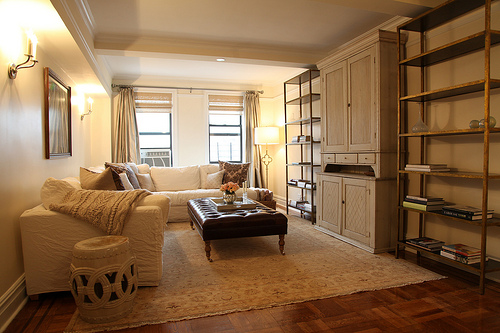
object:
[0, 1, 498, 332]
living room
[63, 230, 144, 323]
basket style table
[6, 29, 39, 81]
sconce lights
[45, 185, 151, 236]
blanket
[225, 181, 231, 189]
flowers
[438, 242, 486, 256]
books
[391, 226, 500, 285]
bottom shelf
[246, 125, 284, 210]
floor lamp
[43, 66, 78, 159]
art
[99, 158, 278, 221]
couch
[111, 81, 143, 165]
curtains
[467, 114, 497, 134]
vase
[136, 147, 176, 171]
air conditioner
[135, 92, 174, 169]
window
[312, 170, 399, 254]
cabinet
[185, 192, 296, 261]
ottoman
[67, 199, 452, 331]
rug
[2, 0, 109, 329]
wall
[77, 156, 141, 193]
pillows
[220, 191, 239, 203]
vase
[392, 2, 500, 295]
bookshelf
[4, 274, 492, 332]
floor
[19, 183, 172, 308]
chair